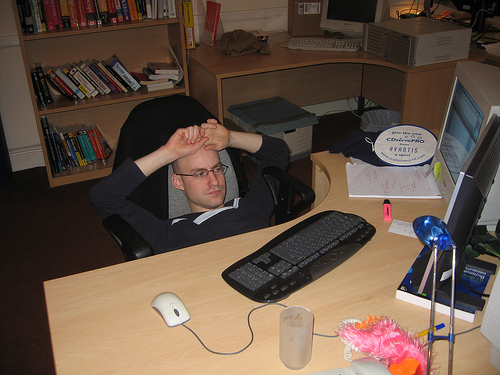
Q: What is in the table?
A: Chair.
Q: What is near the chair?
A: Computer.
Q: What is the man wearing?
A: Jacket.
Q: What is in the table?
A: Seat.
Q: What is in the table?
A: Wire.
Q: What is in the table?
A: Books.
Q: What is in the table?
A: Screen.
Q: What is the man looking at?
A: A grey and black computer monitor.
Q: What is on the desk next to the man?
A: A wireless computer keyboard.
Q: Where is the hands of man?
A: Face.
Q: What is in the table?
A: Mouse.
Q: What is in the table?
A: Key board.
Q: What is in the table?
A: Cloth.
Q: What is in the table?
A: Mike.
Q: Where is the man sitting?
A: At the desk.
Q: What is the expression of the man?
A: Boredom.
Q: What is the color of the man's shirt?
A: Gray and white.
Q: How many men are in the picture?
A: One.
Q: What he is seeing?
A: The computer.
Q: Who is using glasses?
A: The man.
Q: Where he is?
A: In a office.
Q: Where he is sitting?
A: In a chair.